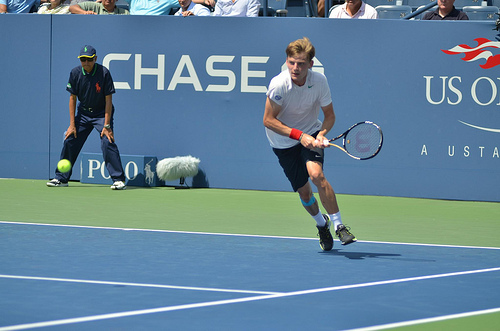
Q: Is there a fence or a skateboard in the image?
A: No, there are no fences or skateboards.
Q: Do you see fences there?
A: No, there are no fences.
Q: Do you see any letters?
A: Yes, there are letters.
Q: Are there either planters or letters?
A: Yes, there are letters.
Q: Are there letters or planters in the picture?
A: Yes, there are letters.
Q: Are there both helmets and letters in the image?
A: No, there are letters but no helmets.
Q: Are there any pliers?
A: No, there are no pliers.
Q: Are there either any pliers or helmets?
A: No, there are no pliers or helmets.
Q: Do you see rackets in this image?
A: Yes, there is a racket.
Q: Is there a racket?
A: Yes, there is a racket.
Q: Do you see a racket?
A: Yes, there is a racket.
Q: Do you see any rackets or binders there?
A: Yes, there is a racket.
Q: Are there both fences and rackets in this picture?
A: No, there is a racket but no fences.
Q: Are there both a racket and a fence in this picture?
A: No, there is a racket but no fences.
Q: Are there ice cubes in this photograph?
A: No, there are no ice cubes.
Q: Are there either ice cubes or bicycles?
A: No, there are no ice cubes or bicycles.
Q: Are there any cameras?
A: No, there are no cameras.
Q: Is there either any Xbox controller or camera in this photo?
A: No, there are no cameras or Xbox controllers.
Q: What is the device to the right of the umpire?
A: The device is a microphone.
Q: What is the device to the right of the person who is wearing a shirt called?
A: The device is a microphone.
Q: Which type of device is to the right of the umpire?
A: The device is a microphone.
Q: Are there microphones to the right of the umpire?
A: Yes, there is a microphone to the right of the umpire.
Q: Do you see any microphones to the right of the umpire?
A: Yes, there is a microphone to the right of the umpire.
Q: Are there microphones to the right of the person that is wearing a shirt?
A: Yes, there is a microphone to the right of the umpire.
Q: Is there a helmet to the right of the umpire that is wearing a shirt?
A: No, there is a microphone to the right of the umpire.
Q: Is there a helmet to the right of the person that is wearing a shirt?
A: No, there is a microphone to the right of the umpire.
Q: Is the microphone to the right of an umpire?
A: Yes, the microphone is to the right of an umpire.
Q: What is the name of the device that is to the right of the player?
A: The device is a microphone.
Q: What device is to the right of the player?
A: The device is a microphone.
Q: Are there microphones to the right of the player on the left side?
A: Yes, there is a microphone to the right of the player.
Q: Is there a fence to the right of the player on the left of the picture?
A: No, there is a microphone to the right of the player.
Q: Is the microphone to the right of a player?
A: Yes, the microphone is to the right of a player.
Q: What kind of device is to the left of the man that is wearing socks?
A: The device is a microphone.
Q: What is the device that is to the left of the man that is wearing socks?
A: The device is a microphone.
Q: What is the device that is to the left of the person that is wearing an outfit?
A: The device is a microphone.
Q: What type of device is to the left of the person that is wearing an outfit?
A: The device is a microphone.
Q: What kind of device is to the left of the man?
A: The device is a microphone.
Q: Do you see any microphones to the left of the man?
A: Yes, there is a microphone to the left of the man.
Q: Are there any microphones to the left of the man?
A: Yes, there is a microphone to the left of the man.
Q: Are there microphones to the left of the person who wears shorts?
A: Yes, there is a microphone to the left of the man.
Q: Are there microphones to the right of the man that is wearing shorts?
A: No, the microphone is to the left of the man.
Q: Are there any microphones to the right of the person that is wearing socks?
A: No, the microphone is to the left of the man.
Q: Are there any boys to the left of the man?
A: No, there is a microphone to the left of the man.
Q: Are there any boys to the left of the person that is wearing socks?
A: No, there is a microphone to the left of the man.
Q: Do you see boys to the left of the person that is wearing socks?
A: No, there is a microphone to the left of the man.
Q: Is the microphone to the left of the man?
A: Yes, the microphone is to the left of the man.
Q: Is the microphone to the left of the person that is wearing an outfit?
A: Yes, the microphone is to the left of the man.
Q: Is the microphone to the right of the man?
A: No, the microphone is to the left of the man.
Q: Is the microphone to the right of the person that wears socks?
A: No, the microphone is to the left of the man.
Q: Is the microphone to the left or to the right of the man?
A: The microphone is to the left of the man.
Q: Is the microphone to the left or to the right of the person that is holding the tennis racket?
A: The microphone is to the left of the man.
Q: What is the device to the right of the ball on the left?
A: The device is a microphone.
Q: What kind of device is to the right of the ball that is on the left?
A: The device is a microphone.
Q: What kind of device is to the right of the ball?
A: The device is a microphone.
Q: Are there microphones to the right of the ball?
A: Yes, there is a microphone to the right of the ball.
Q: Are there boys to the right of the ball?
A: No, there is a microphone to the right of the ball.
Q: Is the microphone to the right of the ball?
A: Yes, the microphone is to the right of the ball.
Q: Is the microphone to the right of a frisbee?
A: No, the microphone is to the right of the ball.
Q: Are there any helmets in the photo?
A: No, there are no helmets.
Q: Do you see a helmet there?
A: No, there are no helmets.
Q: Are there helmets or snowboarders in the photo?
A: No, there are no helmets or snowboarders.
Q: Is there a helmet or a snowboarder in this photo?
A: No, there are no helmets or snowboarders.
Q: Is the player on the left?
A: Yes, the player is on the left of the image.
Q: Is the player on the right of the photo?
A: No, the player is on the left of the image.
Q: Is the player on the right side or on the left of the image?
A: The player is on the left of the image.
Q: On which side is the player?
A: The player is on the left of the image.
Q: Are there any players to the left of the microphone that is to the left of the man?
A: Yes, there is a player to the left of the microphone.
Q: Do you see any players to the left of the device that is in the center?
A: Yes, there is a player to the left of the microphone.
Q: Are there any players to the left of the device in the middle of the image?
A: Yes, there is a player to the left of the microphone.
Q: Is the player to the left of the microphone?
A: Yes, the player is to the left of the microphone.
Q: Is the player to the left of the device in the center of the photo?
A: Yes, the player is to the left of the microphone.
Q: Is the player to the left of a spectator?
A: No, the player is to the left of the microphone.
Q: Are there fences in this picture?
A: No, there are no fences.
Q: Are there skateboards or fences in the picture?
A: No, there are no fences or skateboards.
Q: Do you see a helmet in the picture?
A: No, there are no helmets.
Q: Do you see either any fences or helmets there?
A: No, there are no helmets or fences.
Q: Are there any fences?
A: No, there are no fences.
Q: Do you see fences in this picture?
A: No, there are no fences.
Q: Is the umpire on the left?
A: Yes, the umpire is on the left of the image.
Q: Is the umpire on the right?
A: No, the umpire is on the left of the image.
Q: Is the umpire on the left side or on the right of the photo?
A: The umpire is on the left of the image.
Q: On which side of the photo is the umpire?
A: The umpire is on the left of the image.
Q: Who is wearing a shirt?
A: The umpire is wearing a shirt.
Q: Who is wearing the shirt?
A: The umpire is wearing a shirt.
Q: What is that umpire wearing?
A: The umpire is wearing a shirt.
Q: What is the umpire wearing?
A: The umpire is wearing a shirt.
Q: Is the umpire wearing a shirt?
A: Yes, the umpire is wearing a shirt.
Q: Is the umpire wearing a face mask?
A: No, the umpire is wearing a shirt.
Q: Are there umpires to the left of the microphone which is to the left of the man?
A: Yes, there is an umpire to the left of the microphone.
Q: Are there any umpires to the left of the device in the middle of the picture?
A: Yes, there is an umpire to the left of the microphone.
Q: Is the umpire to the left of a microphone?
A: Yes, the umpire is to the left of a microphone.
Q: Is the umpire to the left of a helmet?
A: No, the umpire is to the left of a microphone.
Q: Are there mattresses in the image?
A: No, there are no mattresses.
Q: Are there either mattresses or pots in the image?
A: No, there are no mattresses or pots.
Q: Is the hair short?
A: Yes, the hair is short.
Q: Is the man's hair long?
A: No, the hair is short.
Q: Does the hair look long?
A: No, the hair is short.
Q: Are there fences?
A: No, there are no fences.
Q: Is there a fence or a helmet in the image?
A: No, there are no fences or helmets.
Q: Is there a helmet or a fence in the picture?
A: No, there are no fences or helmets.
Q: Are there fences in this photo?
A: No, there are no fences.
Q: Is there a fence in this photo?
A: No, there are no fences.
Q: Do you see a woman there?
A: No, there are no women.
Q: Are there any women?
A: No, there are no women.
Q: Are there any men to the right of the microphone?
A: Yes, there is a man to the right of the microphone.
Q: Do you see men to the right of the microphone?
A: Yes, there is a man to the right of the microphone.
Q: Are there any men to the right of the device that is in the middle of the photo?
A: Yes, there is a man to the right of the microphone.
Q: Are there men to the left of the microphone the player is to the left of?
A: No, the man is to the right of the microphone.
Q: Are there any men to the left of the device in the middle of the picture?
A: No, the man is to the right of the microphone.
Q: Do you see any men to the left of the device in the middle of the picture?
A: No, the man is to the right of the microphone.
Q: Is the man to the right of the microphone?
A: Yes, the man is to the right of the microphone.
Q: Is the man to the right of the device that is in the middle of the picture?
A: Yes, the man is to the right of the microphone.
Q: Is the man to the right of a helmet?
A: No, the man is to the right of the microphone.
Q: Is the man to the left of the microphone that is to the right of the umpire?
A: No, the man is to the right of the microphone.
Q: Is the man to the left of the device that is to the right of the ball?
A: No, the man is to the right of the microphone.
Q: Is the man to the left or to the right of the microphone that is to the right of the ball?
A: The man is to the right of the microphone.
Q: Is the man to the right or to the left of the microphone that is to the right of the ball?
A: The man is to the right of the microphone.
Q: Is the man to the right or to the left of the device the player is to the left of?
A: The man is to the right of the microphone.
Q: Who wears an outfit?
A: The man wears an outfit.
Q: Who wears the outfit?
A: The man wears an outfit.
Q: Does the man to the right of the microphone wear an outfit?
A: Yes, the man wears an outfit.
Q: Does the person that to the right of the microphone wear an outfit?
A: Yes, the man wears an outfit.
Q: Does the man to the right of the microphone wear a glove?
A: No, the man wears an outfit.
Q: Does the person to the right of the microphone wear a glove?
A: No, the man wears an outfit.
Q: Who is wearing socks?
A: The man is wearing socks.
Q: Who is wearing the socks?
A: The man is wearing socks.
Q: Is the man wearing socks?
A: Yes, the man is wearing socks.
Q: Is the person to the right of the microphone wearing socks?
A: Yes, the man is wearing socks.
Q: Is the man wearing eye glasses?
A: No, the man is wearing socks.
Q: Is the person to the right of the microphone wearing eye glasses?
A: No, the man is wearing socks.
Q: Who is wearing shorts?
A: The man is wearing shorts.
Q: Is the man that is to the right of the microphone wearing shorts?
A: Yes, the man is wearing shorts.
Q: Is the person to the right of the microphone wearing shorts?
A: Yes, the man is wearing shorts.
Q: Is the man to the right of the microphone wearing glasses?
A: No, the man is wearing shorts.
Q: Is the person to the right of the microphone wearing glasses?
A: No, the man is wearing shorts.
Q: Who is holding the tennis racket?
A: The man is holding the tennis racket.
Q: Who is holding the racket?
A: The man is holding the tennis racket.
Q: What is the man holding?
A: The man is holding the racket.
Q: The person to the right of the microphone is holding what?
A: The man is holding the racket.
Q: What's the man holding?
A: The man is holding the racket.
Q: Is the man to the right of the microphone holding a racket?
A: Yes, the man is holding a racket.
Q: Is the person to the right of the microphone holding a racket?
A: Yes, the man is holding a racket.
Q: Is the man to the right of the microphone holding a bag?
A: No, the man is holding a racket.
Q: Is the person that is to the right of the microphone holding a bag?
A: No, the man is holding a racket.